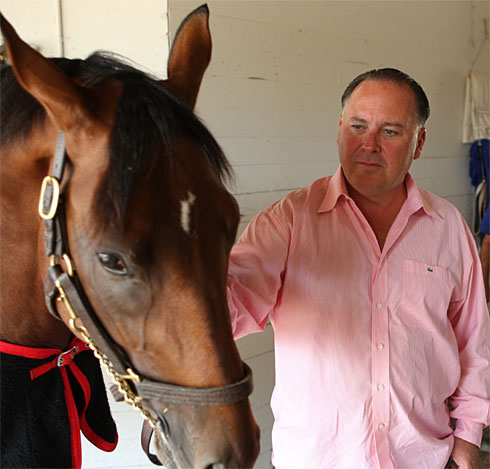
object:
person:
[226, 68, 489, 468]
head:
[334, 68, 427, 205]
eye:
[349, 122, 369, 131]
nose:
[360, 129, 380, 153]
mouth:
[355, 160, 386, 169]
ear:
[412, 128, 423, 161]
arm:
[225, 201, 289, 341]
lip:
[356, 160, 383, 166]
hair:
[341, 68, 430, 126]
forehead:
[340, 79, 412, 127]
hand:
[450, 436, 481, 468]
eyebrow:
[350, 115, 367, 123]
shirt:
[228, 163, 489, 468]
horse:
[0, 0, 261, 468]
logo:
[425, 267, 433, 274]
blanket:
[0, 337, 118, 469]